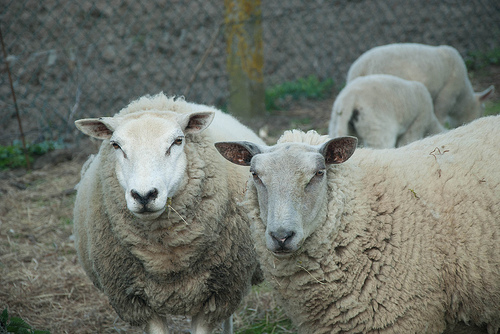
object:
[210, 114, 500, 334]
sheep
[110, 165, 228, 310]
wool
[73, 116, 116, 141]
ears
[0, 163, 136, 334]
hay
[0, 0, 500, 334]
ground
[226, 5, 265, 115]
post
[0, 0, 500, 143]
fence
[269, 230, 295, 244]
nose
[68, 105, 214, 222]
head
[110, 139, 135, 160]
eye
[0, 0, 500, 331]
pen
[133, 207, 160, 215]
mouth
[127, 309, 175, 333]
leg